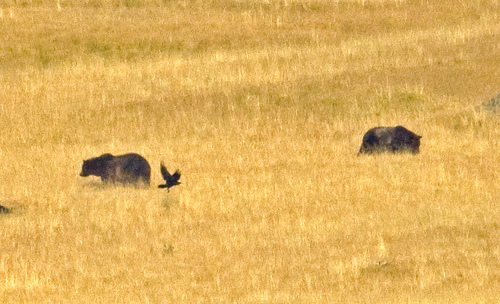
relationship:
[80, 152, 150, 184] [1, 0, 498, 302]
bear in field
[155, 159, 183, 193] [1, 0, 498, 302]
bird in field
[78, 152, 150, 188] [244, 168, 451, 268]
bear in field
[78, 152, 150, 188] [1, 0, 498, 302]
bear in field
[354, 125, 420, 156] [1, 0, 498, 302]
bear in field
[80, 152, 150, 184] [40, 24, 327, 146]
bear in field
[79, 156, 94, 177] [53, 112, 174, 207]
head of bear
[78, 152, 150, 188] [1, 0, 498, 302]
bear of field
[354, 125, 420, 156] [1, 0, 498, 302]
bear of field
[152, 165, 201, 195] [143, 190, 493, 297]
bird over field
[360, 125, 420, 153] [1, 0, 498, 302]
bear in field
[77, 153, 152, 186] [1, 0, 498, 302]
bison in field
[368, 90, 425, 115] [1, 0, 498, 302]
green patch on field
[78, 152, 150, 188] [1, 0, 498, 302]
bear walking on field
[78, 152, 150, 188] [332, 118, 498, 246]
bear looking to left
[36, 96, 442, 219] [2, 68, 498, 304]
creatures in wild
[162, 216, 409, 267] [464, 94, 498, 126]
part of unknown object in grass